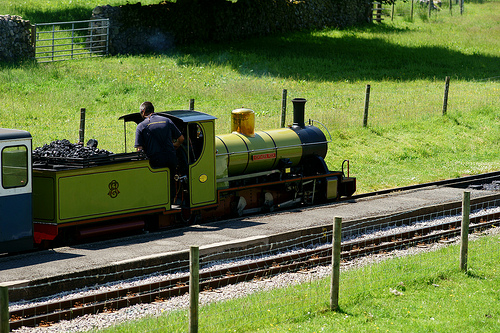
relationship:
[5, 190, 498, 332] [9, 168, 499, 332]
fence beside train tracks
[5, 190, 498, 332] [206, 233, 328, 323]
fence made of wire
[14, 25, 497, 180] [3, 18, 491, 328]
grass on ground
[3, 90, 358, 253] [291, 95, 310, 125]
train has smoke stack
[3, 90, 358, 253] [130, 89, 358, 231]
train has engine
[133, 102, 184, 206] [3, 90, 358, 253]
man riding on train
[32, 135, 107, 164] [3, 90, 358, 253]
coal on top of train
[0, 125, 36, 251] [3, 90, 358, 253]
car attached to train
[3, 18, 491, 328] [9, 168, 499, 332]
ground next to train tracks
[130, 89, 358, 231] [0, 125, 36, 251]
engine pulling car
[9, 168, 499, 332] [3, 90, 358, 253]
train tracks are next to train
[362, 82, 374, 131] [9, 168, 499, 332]
post next to train tracks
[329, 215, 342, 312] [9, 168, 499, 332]
post next to train tracks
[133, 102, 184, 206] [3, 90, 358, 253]
man standing on train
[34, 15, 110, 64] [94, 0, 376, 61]
gate attached to stone wall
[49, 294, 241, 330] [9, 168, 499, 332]
gravel near train tracks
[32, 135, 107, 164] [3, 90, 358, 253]
coal sitting on top of train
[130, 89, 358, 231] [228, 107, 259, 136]
engine has boiler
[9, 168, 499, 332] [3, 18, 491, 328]
train tracks are on ground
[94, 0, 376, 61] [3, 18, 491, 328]
stone wall standing on ground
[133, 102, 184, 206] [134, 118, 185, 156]
man wearing shirt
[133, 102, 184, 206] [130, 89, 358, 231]
man standing on engine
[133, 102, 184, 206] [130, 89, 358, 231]
man on top of engine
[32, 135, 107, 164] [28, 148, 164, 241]
coal on car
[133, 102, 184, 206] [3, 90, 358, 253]
man working on train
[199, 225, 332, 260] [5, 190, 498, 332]
barbed wire on fence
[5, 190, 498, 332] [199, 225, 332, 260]
fence has barbed wire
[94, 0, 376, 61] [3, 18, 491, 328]
stone wall sitting on ground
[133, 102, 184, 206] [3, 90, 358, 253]
man on top of train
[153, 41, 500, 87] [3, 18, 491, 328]
shadow on ground